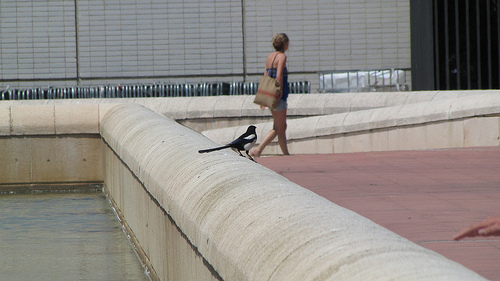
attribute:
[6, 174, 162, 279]
water — still, dirty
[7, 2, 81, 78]
bricks — grey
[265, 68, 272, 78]
top — tank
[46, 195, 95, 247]
water — part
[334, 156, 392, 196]
ground — part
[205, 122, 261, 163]
bird — part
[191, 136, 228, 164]
tail — bird's, part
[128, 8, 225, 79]
building — part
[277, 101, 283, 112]
shorts — blue, part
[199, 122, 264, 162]
bird — black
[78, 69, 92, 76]
brick — white 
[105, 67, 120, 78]
brick — white 